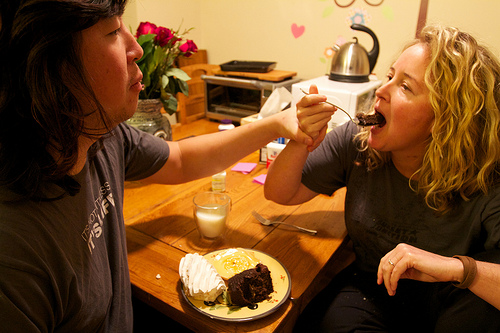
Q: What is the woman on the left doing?
A: Feeding the girl.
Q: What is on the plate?
A: Cake and icecream.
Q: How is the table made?
A: Of wood.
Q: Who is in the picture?
A: A woman and a girl.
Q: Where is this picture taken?
A: A kitchen.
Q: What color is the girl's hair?
A: Blonde.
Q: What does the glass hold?
A: Milk.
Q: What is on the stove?
A: A kettle.